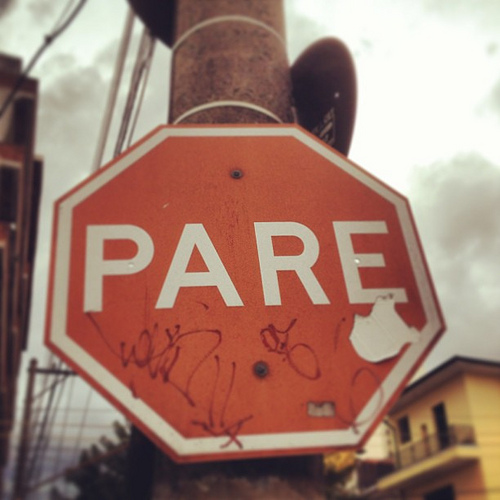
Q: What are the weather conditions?
A: It is cloudy.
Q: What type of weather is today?
A: It is cloudy.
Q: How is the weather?
A: It is cloudy.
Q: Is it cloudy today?
A: Yes, it is cloudy.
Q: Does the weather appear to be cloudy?
A: Yes, it is cloudy.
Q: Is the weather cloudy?
A: Yes, it is cloudy.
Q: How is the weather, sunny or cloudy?
A: It is cloudy.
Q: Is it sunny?
A: No, it is cloudy.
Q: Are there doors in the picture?
A: Yes, there is a door.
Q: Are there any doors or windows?
A: Yes, there is a door.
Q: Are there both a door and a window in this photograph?
A: Yes, there are both a door and a window.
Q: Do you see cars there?
A: No, there are no cars.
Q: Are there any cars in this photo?
A: No, there are no cars.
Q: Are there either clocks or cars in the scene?
A: No, there are no cars or clocks.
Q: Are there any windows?
A: Yes, there are windows.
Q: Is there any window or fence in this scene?
A: Yes, there are windows.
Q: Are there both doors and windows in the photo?
A: Yes, there are both windows and a door.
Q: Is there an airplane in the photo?
A: No, there are no airplanes.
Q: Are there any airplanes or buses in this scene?
A: No, there are no airplanes or buses.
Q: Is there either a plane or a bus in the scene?
A: No, there are no airplanes or buses.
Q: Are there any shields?
A: No, there are no shields.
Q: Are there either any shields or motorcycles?
A: No, there are no shields or motorcycles.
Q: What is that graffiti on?
A: The graffiti is on the sign.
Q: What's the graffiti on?
A: The graffiti is on the sign.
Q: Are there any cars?
A: No, there are no cars.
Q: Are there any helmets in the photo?
A: No, there are no helmets.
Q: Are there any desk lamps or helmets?
A: No, there are no helmets or desk lamps.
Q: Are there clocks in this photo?
A: No, there are no clocks.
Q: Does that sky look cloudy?
A: Yes, the sky is cloudy.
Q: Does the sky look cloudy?
A: Yes, the sky is cloudy.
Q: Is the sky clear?
A: No, the sky is cloudy.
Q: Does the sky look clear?
A: No, the sky is cloudy.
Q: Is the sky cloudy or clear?
A: The sky is cloudy.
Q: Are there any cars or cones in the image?
A: No, there are no cars or cones.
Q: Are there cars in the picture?
A: No, there are no cars.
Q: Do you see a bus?
A: No, there are no buses.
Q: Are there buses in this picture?
A: No, there are no buses.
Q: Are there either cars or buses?
A: No, there are no buses or cars.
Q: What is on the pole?
A: The sign is on the pole.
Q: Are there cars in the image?
A: No, there are no cars.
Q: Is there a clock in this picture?
A: No, there are no clocks.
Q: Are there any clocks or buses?
A: No, there are no clocks or buses.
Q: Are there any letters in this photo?
A: Yes, there are letters.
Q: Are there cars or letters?
A: Yes, there are letters.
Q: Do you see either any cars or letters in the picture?
A: Yes, there are letters.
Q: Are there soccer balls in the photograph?
A: No, there are no soccer balls.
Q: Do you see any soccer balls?
A: No, there are no soccer balls.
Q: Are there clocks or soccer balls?
A: No, there are no soccer balls or clocks.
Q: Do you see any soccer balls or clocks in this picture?
A: No, there are no soccer balls or clocks.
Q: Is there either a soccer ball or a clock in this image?
A: No, there are no soccer balls or clocks.